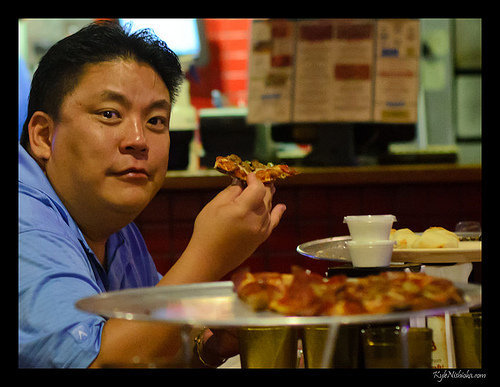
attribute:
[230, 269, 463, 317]
pizza — half eaten, sliced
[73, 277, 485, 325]
baking sheet — silver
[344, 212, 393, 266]
containers — small, plastic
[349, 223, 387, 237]
sauce — dipping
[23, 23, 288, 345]
man — asian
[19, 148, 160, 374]
shirt — blue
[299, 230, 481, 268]
baking sheet — silver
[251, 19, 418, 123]
menu — in distance, blurry, in background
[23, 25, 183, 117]
hair — black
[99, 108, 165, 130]
eyes — brown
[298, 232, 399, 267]
pizza pie — finished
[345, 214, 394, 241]
dressing — side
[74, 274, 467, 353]
platter — metal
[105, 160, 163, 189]
smile — small